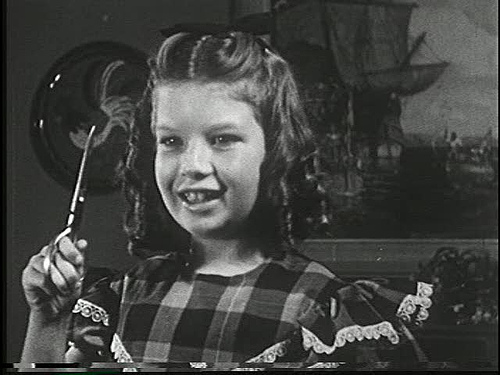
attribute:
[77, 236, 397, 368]
dress — plaid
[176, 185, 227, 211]
smile — buck-toothed